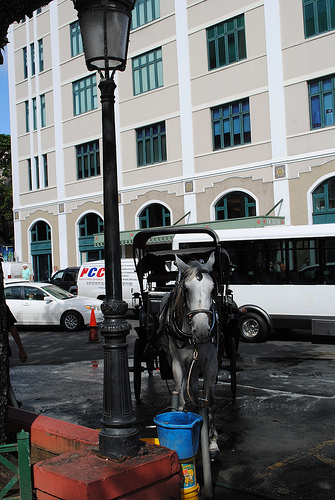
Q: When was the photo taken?
A: Daytime.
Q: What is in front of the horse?
A: Buckets.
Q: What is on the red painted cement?
A: Lamp post.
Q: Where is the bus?
A: Behind the horse.